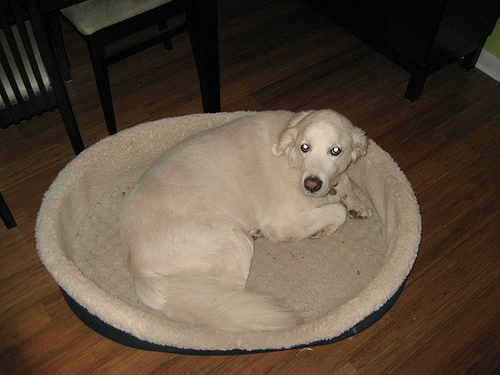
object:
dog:
[116, 107, 376, 333]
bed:
[34, 106, 423, 355]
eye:
[299, 143, 312, 153]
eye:
[330, 146, 345, 158]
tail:
[161, 288, 302, 333]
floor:
[0, 1, 499, 374]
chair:
[43, 0, 223, 136]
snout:
[300, 171, 328, 194]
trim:
[475, 50, 499, 77]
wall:
[486, 26, 499, 55]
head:
[276, 108, 367, 197]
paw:
[343, 196, 371, 221]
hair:
[145, 233, 164, 247]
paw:
[310, 228, 333, 241]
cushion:
[59, 0, 169, 36]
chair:
[0, 0, 87, 230]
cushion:
[0, 20, 53, 111]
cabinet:
[305, 0, 499, 104]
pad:
[349, 208, 358, 216]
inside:
[62, 194, 113, 254]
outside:
[68, 299, 112, 335]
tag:
[328, 187, 337, 195]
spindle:
[10, 0, 51, 100]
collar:
[334, 183, 340, 187]